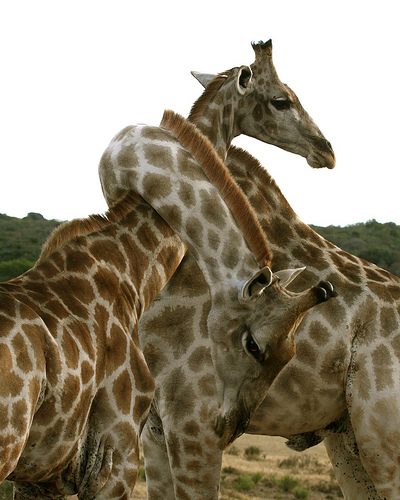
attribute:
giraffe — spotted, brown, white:
[2, 49, 338, 475]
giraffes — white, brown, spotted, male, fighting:
[0, 35, 399, 497]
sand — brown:
[223, 445, 338, 498]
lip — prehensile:
[205, 415, 231, 455]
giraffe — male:
[108, 75, 398, 445]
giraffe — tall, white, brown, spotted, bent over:
[188, 260, 346, 451]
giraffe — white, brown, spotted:
[185, 27, 337, 176]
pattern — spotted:
[48, 262, 150, 396]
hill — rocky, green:
[0, 211, 398, 281]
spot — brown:
[136, 221, 160, 253]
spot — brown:
[60, 328, 80, 370]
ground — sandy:
[236, 463, 281, 479]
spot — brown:
[174, 182, 233, 231]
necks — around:
[56, 93, 344, 310]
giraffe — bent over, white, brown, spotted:
[98, 111, 335, 450]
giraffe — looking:
[70, 33, 396, 492]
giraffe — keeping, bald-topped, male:
[7, 39, 336, 394]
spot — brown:
[58, 369, 88, 415]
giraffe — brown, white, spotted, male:
[98, 113, 398, 494]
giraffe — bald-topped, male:
[156, 207, 398, 499]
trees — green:
[2, 208, 64, 279]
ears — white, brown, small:
[186, 59, 274, 94]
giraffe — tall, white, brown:
[176, 48, 367, 249]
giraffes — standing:
[16, 28, 345, 438]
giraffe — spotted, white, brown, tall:
[1, 55, 359, 496]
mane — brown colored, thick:
[160, 107, 273, 267]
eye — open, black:
[272, 96, 293, 112]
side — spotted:
[36, 255, 145, 429]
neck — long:
[97, 120, 236, 305]